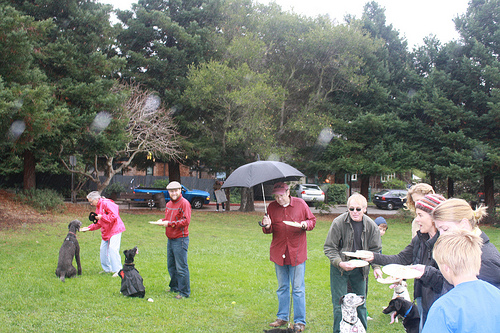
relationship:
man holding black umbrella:
[262, 182, 314, 332] [221, 159, 306, 227]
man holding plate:
[157, 181, 192, 300] [147, 211, 163, 228]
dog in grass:
[51, 214, 81, 286] [36, 210, 498, 327]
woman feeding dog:
[85, 182, 121, 275] [45, 222, 94, 281]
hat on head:
[402, 180, 444, 213] [410, 194, 445, 235]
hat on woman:
[402, 180, 444, 213] [349, 197, 437, 323]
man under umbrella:
[262, 184, 317, 332] [214, 153, 305, 195]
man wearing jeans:
[157, 181, 192, 300] [166, 233, 195, 287]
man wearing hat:
[162, 177, 192, 300] [165, 180, 185, 191]